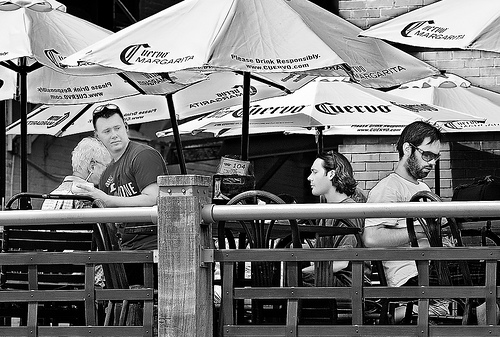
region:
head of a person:
[78, 77, 155, 153]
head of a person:
[50, 120, 140, 196]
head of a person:
[297, 140, 377, 190]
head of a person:
[381, 110, 467, 185]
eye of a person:
[410, 139, 457, 160]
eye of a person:
[299, 153, 334, 177]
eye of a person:
[76, 112, 144, 140]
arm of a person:
[100, 161, 167, 221]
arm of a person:
[365, 211, 459, 246]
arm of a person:
[285, 229, 363, 294]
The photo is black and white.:
[36, 18, 448, 303]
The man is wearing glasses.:
[410, 132, 447, 163]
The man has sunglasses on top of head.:
[308, 141, 343, 173]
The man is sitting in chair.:
[368, 119, 466, 279]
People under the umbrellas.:
[70, 48, 442, 222]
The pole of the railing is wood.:
[143, 173, 215, 325]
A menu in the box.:
[213, 154, 268, 191]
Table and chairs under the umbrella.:
[223, 187, 376, 294]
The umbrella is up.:
[112, 7, 406, 111]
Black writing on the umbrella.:
[304, 84, 414, 120]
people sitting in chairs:
[15, 50, 482, 335]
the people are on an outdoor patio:
[21, 64, 498, 291]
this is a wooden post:
[147, 161, 227, 334]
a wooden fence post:
[147, 165, 244, 331]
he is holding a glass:
[47, 89, 191, 262]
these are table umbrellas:
[2, 2, 497, 135]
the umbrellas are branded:
[1, 0, 484, 143]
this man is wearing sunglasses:
[374, 110, 479, 238]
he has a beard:
[375, 83, 486, 298]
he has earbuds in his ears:
[67, 90, 182, 240]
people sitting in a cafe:
[54, 109, 479, 261]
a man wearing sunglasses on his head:
[64, 102, 130, 123]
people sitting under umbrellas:
[27, 58, 454, 253]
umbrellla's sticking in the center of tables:
[28, 42, 431, 281]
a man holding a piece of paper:
[45, 164, 126, 214]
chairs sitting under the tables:
[213, 180, 325, 325]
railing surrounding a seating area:
[54, 205, 446, 331]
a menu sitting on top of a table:
[217, 153, 264, 208]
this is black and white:
[6, 30, 498, 260]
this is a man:
[65, 97, 165, 192]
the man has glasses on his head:
[86, 106, 123, 112]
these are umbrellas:
[23, 1, 443, 163]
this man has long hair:
[276, 169, 374, 210]